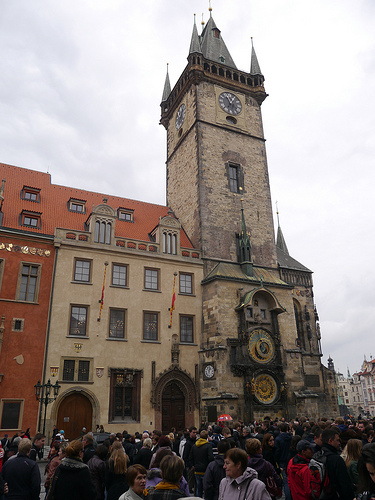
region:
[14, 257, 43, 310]
The window is rectangular.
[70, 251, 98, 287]
The window is rectangular.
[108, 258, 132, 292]
The window is rectangular.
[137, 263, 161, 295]
The window is rectangular.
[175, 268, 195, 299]
The window is rectangular.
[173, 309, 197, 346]
The window is rectangular.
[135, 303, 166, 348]
The window is rectangular.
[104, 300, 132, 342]
The window is rectangular.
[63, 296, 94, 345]
The window is rectangular.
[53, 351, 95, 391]
The window is rectangular.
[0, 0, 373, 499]
scene is old town square in prague, czech republic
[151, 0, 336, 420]
building is old town tower & astronomical clock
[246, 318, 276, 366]
astronomical clock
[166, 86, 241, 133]
regular old ordinary clock in a glockenspiel, just really high up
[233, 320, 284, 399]
figures--the apostles--beside the clock are hard to discern due to distance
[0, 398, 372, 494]
a crowd gathered in prague, old town centre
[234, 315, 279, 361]
third oldest astronomical clock in existence, & oldest working astronomical clock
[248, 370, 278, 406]
calendar plate below the clock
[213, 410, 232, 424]
a small, high red umbrella, w/ a white, probably figural pattern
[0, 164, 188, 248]
The roof is red.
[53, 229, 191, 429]
The building is tan.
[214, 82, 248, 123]
The clock face is black.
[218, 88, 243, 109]
The numbers are white.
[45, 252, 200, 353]
The windows are small.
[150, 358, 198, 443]
The doorway is arched.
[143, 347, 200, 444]
The door is closed.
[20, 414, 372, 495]
The people are walking.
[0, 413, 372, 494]
There are many people.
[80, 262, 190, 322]
The flags are on the side of the building.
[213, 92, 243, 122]
black and white clock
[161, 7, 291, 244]
brown clock tower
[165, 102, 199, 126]
white and black clock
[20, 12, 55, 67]
white clouds in blue sky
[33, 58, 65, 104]
white clouds in blue sky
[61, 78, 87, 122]
white clouds in blue sky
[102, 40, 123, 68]
white clouds in blue sky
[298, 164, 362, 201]
white clouds in blue sky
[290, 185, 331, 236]
white clouds in blue sky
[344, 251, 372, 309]
white clouds in blue sky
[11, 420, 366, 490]
a large crowd of people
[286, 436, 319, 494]
a person wearing a red jacket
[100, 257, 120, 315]
a red and yellow wand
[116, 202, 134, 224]
a small attic window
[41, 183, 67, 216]
red tiles on the roof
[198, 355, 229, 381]
a small white clock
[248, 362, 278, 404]
a large golden clock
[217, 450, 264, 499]
a woman wearing a tan coat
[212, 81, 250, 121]
a black clock on the tower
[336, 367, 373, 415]
a palace in the distance